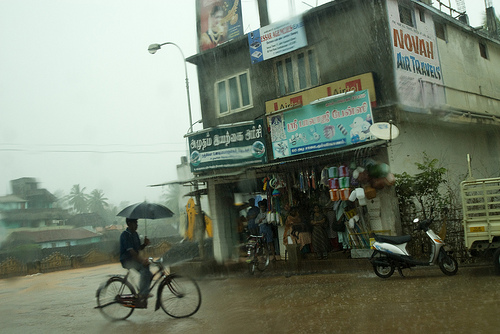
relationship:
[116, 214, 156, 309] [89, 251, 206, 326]
man riding bike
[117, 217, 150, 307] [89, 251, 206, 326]
man riding bike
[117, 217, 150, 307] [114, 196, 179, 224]
man holding umbrella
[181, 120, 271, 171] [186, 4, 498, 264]
signs on front of building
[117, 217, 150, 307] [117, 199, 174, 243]
man holding umbrella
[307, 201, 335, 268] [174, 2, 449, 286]
girl standing in front of store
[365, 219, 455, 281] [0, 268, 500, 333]
moped parked on ground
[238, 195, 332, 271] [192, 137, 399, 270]
people waiting in shop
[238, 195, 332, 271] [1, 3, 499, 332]
people avoid getting wet from rain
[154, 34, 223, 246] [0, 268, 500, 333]
lamp post on ground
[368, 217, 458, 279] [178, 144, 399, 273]
moped parked in front of shop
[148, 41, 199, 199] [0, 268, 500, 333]
post light on ground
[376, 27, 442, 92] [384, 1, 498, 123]
advertisement on wall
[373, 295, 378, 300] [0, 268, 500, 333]
droplet of water on ground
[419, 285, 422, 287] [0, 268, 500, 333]
droplet of water on ground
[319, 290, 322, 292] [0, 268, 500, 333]
droplet of water on ground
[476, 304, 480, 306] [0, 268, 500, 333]
droplet of water on ground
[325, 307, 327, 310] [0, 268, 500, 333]
droplet of water on ground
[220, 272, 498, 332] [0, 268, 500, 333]
water droplets on ground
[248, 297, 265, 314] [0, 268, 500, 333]
droplets of water on ground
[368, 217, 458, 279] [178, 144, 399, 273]
moped parked outside shop